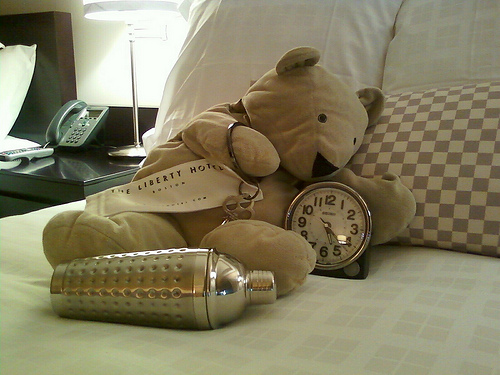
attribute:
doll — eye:
[36, 44, 421, 314]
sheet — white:
[279, 264, 490, 361]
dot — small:
[317, 113, 327, 124]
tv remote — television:
[6, 132, 62, 198]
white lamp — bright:
[81, 2, 181, 157]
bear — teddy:
[121, 36, 381, 303]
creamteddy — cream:
[41, 44, 417, 288]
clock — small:
[277, 183, 379, 291]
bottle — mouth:
[51, 242, 287, 335]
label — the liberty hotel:
[69, 154, 251, 225]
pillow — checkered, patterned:
[360, 90, 494, 255]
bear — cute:
[44, 46, 416, 298]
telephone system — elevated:
[44, 93, 106, 146]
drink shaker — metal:
[43, 244, 279, 332]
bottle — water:
[74, 242, 261, 324]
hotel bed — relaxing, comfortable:
[1, 199, 499, 374]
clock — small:
[281, 180, 377, 280]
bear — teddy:
[47, 60, 407, 272]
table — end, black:
[66, 158, 101, 185]